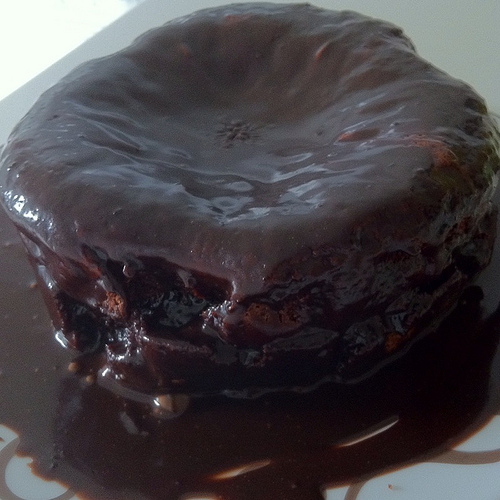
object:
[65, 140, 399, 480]
chocolate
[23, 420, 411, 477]
plate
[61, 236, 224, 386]
dip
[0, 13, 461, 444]
cake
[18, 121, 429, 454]
cake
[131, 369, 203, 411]
bubble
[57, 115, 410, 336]
chocolate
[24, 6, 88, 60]
white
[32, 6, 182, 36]
background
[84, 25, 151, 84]
shadow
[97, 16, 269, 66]
cast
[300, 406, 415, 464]
white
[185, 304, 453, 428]
chocolate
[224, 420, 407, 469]
plate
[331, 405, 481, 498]
line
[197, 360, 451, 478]
plate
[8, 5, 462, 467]
dessert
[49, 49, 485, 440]
cupcake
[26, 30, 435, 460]
dessert cake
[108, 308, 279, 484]
sauce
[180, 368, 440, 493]
plate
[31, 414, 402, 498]
sauce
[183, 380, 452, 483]
plate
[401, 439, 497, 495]
corner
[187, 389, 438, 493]
plate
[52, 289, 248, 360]
pastry crumb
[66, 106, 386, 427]
cake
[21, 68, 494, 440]
cake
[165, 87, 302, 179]
icing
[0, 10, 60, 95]
edge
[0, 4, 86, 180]
table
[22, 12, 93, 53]
background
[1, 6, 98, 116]
table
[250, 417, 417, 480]
plate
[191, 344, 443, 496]
sauce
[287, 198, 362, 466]
chocolate cake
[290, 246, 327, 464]
layers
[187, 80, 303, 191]
dip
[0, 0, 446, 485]
cake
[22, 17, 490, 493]
dessert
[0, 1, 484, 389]
small/chocolate cake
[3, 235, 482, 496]
chocolate syrup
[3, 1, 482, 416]
baked/chocolate desert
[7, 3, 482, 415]
thick/chocolate desert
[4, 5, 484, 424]
chocolate desert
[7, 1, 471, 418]
desert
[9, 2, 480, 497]
desert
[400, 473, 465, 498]
clear plate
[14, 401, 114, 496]
reflective plate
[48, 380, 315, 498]
reflections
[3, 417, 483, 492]
clear plate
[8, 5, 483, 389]
chocolate dessert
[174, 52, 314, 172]
dip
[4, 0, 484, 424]
food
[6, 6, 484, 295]
chocolate frosting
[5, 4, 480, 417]
dessert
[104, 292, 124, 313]
light brown/part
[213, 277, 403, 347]
dark brown/edge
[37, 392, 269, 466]
dessert sauce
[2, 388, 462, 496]
plate